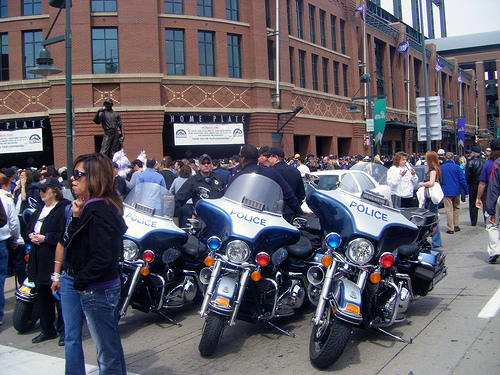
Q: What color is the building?
A: Red.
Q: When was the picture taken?
A: Daytime.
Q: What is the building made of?
A: Bricks.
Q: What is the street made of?
A: Pavement.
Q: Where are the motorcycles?
A: On the street.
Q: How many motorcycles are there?
A: Four.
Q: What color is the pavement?
A: Gray.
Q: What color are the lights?
A: Red, blue, and orange.